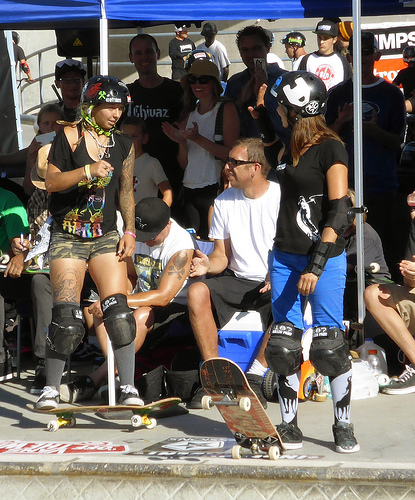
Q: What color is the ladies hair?
A: Brown.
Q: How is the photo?
A: Clear.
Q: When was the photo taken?
A: Daytime.